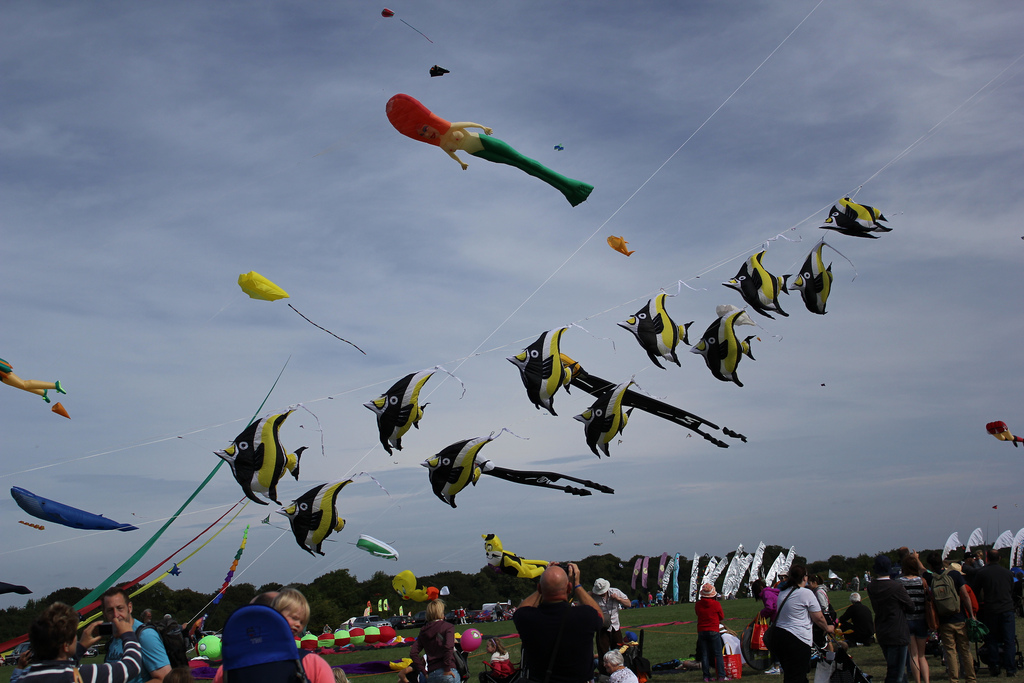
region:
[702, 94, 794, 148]
white clouds in the blue sky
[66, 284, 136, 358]
white clouds in the blue sky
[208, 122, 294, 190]
white clouds in the blue sky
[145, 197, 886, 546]
kites in air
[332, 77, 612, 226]
kites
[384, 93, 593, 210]
a mermaid kite in the sky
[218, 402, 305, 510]
a tropical fish kite in the sky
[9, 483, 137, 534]
a whale kite in the sky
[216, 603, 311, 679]
a backpack child carrier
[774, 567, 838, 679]
a woman in a white t-shirt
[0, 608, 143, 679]
a woman in a stripped shirt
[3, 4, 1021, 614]
a dark cloudy sky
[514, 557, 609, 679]
a bald man in a black shirt holding a camera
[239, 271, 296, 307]
a yellow kite in the sky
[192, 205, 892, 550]
a school of kite flying fish are over a crowd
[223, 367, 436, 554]
the fish are yellow and white striped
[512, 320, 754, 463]
the kite has a long tail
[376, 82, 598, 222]
a mermaid kite is flying near the fish kites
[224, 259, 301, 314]
a yellow seashell kite has a tail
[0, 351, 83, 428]
the legs of a swimmer kite is near a whale kite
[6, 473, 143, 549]
the whale kite is blue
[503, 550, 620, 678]
a man is taking a picture with his camera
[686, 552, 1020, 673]
a crowd of people are watching the kites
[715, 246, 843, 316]
kite in the sky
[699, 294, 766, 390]
kite in the sky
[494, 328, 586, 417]
kite in the sky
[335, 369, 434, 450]
kite in the sky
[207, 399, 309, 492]
kite in the sky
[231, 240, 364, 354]
kite in the sky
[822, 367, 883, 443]
white clouds in the blue sky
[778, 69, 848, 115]
white clouds in the blue sky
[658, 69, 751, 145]
white clouds in the blue sky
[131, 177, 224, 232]
white clouds in the blue sky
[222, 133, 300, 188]
white clouds in the blue sky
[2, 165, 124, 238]
white clouds in the blue sky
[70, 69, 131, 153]
white clouds in the blue sky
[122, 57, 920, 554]
kites in sky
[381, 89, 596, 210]
red beige green mermaid kite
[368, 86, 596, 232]
large colorful kite in sky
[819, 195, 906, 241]
large blue yellow and white kite in sky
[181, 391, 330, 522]
large blue yellow and white kite in sky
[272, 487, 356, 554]
large blue yellow and white kite in sky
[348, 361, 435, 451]
large blue yellow and white kite in sky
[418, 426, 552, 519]
large blue yellow and white kite in sky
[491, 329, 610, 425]
large blue yellow and white kite in sky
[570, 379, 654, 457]
large blue yellow and white kite in sky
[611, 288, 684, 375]
large blue yellow and white kite in sky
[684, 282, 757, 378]
large blue yellow and white kite in sky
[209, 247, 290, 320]
large kite flown in blue sky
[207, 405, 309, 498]
blue yellow and white kite shaped like fish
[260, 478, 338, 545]
blue yellow and white kite shaped like fish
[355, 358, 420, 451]
blue yellow and white kite shaped like fish